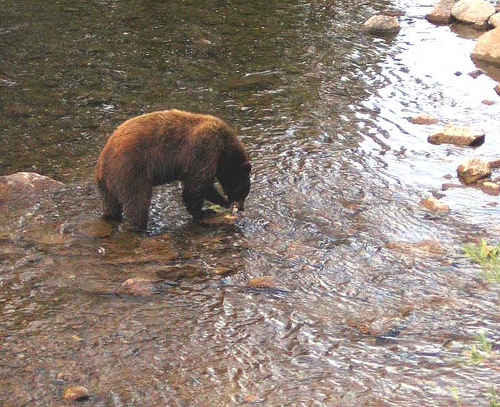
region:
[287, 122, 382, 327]
Small ripples in the water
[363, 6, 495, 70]
Large group of river rock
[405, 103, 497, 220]
Large group of river rock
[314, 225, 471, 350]
Large group of river rock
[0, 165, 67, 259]
one single river rock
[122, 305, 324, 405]
Ripples in the river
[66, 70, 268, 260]
Large brown bear in water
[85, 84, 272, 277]
Large brown bear hunting fish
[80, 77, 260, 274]
Large brown bear fising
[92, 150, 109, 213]
Small brown tail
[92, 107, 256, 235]
Brown spot in water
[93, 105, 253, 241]
Brown bear looking down at water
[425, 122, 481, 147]
Large rock on water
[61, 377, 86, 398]
Large rock on water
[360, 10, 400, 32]
Large rock on water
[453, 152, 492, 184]
Large rock on water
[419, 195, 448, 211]
Large rock on water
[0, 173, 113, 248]
Large rock on water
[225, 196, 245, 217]
Mouth of bear is opened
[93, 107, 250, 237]
Brown fur on bear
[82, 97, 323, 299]
the bear is drinking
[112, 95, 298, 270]
a brown bear at the river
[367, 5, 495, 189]
rocks on the water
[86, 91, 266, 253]
bear eating a fish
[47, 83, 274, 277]
bear fishing in a stream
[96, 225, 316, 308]
rocks below water surface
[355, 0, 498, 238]
reflection on the water surface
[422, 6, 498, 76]
rocks jutting out of the water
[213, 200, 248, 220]
fish in the mouth of a bear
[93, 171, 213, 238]
three legs in the water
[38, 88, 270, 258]
brown bear at mealtime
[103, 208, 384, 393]
ripples on the surface of the water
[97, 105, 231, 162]
dry hair on the back of the bear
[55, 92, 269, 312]
Brown bear in a stream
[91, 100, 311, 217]
Brown bear looking for food in a stream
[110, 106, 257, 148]
Brown bear's back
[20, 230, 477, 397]
Stream with rocks in it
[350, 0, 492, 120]
Big rocks on top of the stream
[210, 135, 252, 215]
Brown bear's head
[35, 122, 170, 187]
Brown bear's back side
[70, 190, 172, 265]
Brown bear's hind legs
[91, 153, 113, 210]
Brown bear's tail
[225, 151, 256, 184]
Brown bear's ear